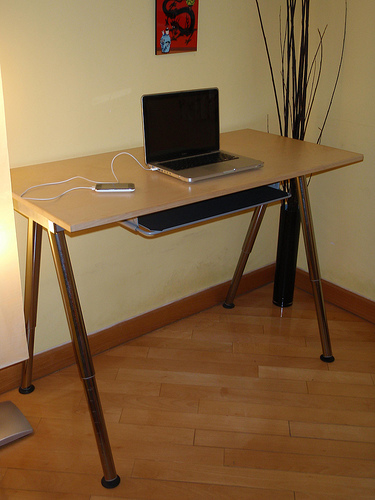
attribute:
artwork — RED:
[155, 1, 198, 54]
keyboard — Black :
[156, 150, 237, 172]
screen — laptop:
[142, 97, 226, 148]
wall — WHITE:
[290, 2, 374, 325]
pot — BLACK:
[268, 186, 307, 309]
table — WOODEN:
[10, 128, 363, 233]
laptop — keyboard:
[135, 86, 263, 182]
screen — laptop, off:
[142, 90, 228, 160]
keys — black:
[153, 147, 236, 172]